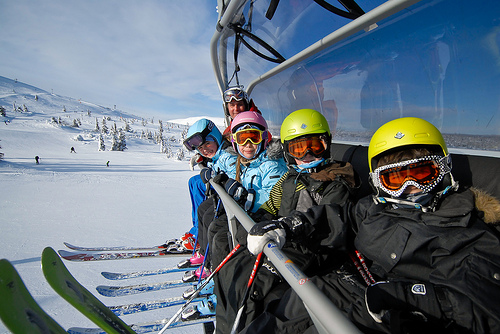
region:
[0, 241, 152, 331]
THE SKIS ARE GREEN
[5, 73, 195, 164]
THE TREES ARE EVERGREENS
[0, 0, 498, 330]
THE KIDS ARE ON THE LIFT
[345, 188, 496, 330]
THE KID IS WEARING A BLACK JACKET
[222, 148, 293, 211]
THE KID IS WEARING A BLUE JACKET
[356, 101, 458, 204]
THE KID IS WEARING A BRIGHT YELLOW HELMET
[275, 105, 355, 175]
THE KID IS WEARING A LIME GREEN HELMET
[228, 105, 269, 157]
THE KID IS WEARING A PINK HELMET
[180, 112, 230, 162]
THE KID IS WEARING A BLUE HELMET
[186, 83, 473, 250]
THE KIDS ARE WEARING GOGGLES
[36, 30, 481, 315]
People are on a ski lift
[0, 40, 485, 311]
Skiers are riding the ski lift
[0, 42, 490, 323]
People are at the ski resort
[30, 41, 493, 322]
The people are having some fun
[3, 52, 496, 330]
The people are all happy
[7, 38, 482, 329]
People are enjoying the winter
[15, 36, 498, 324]
The people are enjoying their day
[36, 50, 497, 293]
People are wearing helmets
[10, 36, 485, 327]
The people are wearing goggles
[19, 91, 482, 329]
The people are wearing warm clothing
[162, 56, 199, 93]
part of a cloud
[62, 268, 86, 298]
part of a boaed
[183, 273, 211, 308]
part of a metsl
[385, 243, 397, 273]
prt of a button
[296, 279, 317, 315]
part of a plastic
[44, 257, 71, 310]
edge of a board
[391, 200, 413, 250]
part of a pocket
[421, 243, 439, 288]
part of a jacket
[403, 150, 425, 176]
part of a glass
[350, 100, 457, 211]
THIS KID IS WEARING A YELLOW HELMET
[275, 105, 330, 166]
THIS KID IS WEARING A GREEN HELMET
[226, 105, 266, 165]
THIS GIRL IS WEARING A PINK HELMET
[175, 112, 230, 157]
THIS WOMAN IS WEARING A BLUE HELMET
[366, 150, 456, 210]
THIS KID IS WEARING GOGGLES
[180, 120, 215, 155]
THIS GIRL IS WEARING HER GOGGLES ON HER HELMET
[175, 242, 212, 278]
THESE BOOTS ARE PINK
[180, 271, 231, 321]
THESE BOOTS ARE BLUE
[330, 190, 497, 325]
THIS JACKET IS BLACK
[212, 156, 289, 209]
THIS JACKET IS BLUE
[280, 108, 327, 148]
A lime green helmet.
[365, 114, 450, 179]
A yellow helmet.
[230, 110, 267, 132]
A pink helmet.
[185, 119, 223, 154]
A blue helmet.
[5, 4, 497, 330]
Five people riding on a ski lift.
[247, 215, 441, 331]
Black and white ski gloves.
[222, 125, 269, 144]
A pair of yellow framed goggles.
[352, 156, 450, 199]
White and black framed ski goggles.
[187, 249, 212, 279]
A pair of pink ski boots.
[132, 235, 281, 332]
Red, black, and white ski poles.